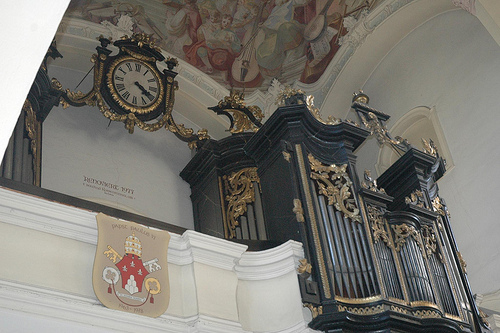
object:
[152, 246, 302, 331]
wall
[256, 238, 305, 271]
paint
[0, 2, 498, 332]
building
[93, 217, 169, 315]
badge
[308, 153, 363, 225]
design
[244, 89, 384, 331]
column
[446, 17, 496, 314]
wall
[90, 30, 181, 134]
clock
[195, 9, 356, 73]
ceiling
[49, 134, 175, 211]
wall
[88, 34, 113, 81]
trim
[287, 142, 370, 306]
line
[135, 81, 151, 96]
hands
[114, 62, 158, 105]
numerals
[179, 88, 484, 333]
wall unit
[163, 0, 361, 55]
roof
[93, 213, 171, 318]
plaque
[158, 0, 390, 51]
design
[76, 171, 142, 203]
writing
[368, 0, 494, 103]
paint